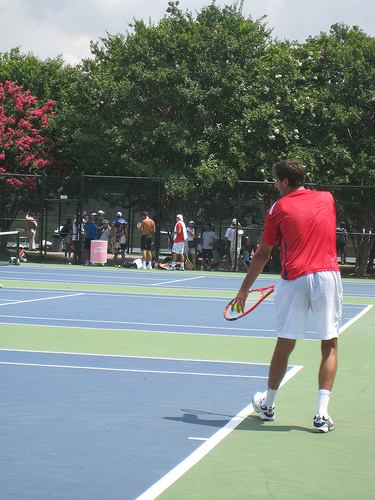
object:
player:
[239, 152, 344, 424]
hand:
[230, 291, 246, 314]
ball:
[232, 303, 240, 311]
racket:
[227, 287, 280, 323]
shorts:
[273, 272, 340, 343]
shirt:
[266, 190, 341, 277]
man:
[138, 212, 156, 267]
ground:
[29, 276, 341, 459]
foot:
[253, 379, 275, 425]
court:
[46, 361, 221, 436]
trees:
[48, 26, 352, 183]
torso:
[136, 219, 154, 238]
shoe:
[253, 388, 275, 418]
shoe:
[310, 412, 333, 432]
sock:
[264, 387, 278, 407]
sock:
[317, 391, 329, 416]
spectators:
[66, 207, 245, 267]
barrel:
[88, 237, 111, 264]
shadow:
[166, 409, 321, 436]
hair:
[272, 160, 308, 186]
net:
[1, 228, 25, 266]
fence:
[53, 174, 246, 266]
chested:
[135, 217, 157, 235]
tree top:
[125, 2, 277, 36]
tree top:
[273, 20, 373, 58]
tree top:
[73, 12, 172, 66]